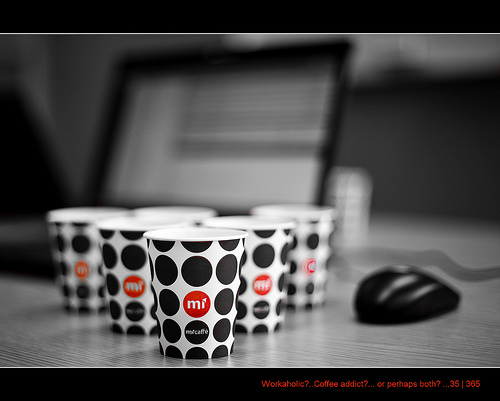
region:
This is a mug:
[145, 217, 245, 369]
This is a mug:
[93, 210, 163, 349]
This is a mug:
[46, 191, 133, 318]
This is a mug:
[209, 193, 301, 340]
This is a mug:
[251, 190, 345, 318]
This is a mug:
[136, 185, 216, 336]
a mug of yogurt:
[42, 182, 129, 321]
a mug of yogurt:
[91, 184, 191, 346]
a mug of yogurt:
[141, 203, 252, 363]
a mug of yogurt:
[203, 187, 297, 342]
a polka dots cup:
[143, 225, 248, 365]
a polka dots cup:
[229, 220, 284, 328]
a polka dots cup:
[290, 203, 343, 321]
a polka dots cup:
[89, 213, 144, 322]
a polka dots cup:
[56, 207, 107, 307]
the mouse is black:
[351, 260, 461, 323]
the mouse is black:
[339, 229, 454, 360]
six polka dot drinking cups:
[45, 198, 354, 330]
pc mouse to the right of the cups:
[358, 255, 452, 329]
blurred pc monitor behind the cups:
[105, 42, 337, 251]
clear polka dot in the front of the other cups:
[139, 222, 249, 372]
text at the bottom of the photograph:
[256, 373, 493, 400]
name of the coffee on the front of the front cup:
[180, 286, 227, 348]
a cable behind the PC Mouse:
[337, 232, 498, 278]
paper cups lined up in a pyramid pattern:
[44, 197, 349, 355]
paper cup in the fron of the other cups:
[145, 229, 235, 367]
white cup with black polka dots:
[141, 225, 263, 361]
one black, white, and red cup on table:
[138, 223, 253, 362]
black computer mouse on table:
[342, 245, 476, 334]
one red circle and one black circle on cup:
[178, 284, 218, 346]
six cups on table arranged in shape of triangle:
[40, 186, 343, 361]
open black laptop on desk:
[8, 29, 362, 298]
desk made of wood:
[3, 183, 497, 378]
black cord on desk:
[331, 236, 495, 286]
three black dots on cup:
[151, 250, 239, 287]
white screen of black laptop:
[104, 73, 331, 206]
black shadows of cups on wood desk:
[6, 305, 163, 369]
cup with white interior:
[145, 222, 241, 355]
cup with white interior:
[90, 218, 155, 333]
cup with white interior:
[52, 208, 105, 308]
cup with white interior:
[215, 212, 285, 331]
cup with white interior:
[260, 205, 329, 308]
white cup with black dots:
[147, 223, 242, 358]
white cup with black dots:
[214, 218, 284, 330]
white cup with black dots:
[255, 202, 332, 312]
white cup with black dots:
[100, 220, 166, 332]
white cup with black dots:
[60, 215, 102, 316]